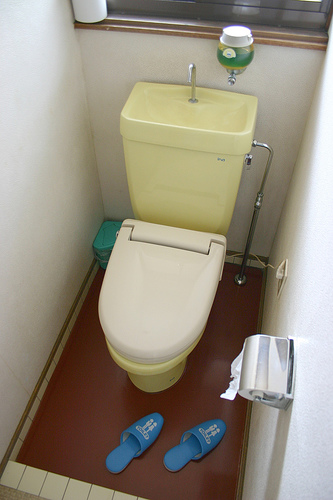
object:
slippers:
[106, 411, 164, 475]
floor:
[2, 374, 249, 500]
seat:
[93, 219, 229, 384]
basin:
[114, 358, 191, 391]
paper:
[219, 344, 244, 414]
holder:
[236, 331, 298, 412]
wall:
[293, 175, 332, 405]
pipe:
[235, 138, 281, 301]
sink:
[107, 63, 261, 168]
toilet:
[94, 82, 259, 394]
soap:
[214, 23, 258, 70]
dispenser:
[216, 25, 256, 86]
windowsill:
[122, 13, 216, 38]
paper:
[69, 0, 110, 22]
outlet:
[269, 257, 288, 297]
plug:
[273, 263, 283, 281]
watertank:
[118, 143, 247, 221]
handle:
[245, 149, 254, 169]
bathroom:
[0, 0, 331, 498]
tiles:
[21, 464, 81, 499]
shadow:
[259, 404, 294, 498]